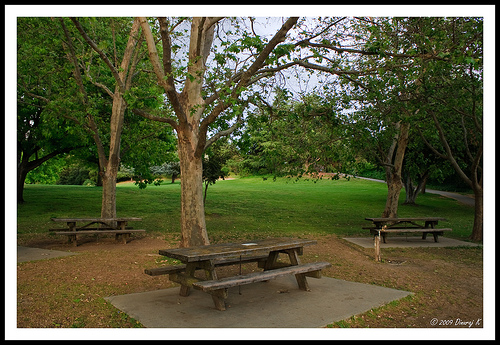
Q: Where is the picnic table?
A: On a concrete slab.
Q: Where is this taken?
A: In a park.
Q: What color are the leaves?
A: Green.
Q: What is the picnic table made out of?
A: Wood.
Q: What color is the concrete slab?
A: Grey.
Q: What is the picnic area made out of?
A: Grass and dirt.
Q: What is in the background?
A: A field of cut grass.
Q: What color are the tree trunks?
A: Light brown.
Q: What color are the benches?
A: Brown.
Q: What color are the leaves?
A: Green.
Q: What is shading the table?
A: Trees.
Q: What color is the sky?
A: Blue.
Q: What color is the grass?
A: Green.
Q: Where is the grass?
A: Behind the tables.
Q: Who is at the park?
A: No one.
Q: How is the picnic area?
A: Clean.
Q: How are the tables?
A: Worn.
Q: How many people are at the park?
A: None.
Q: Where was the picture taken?
A: A park.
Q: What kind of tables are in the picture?
A: Picnic tables.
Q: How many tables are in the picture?
A: Three.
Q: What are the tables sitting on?
A: Concrete.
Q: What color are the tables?
A: Brown.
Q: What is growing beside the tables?
A: Trees.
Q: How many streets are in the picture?
A: One.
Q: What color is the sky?
A: Blue.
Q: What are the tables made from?
A: Wood.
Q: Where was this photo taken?
A: In a park.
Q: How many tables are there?
A: Three.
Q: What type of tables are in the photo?
A: Picnic tables.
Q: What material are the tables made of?
A: Wood.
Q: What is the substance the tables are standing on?
A: Concrete.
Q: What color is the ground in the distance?
A: Green.